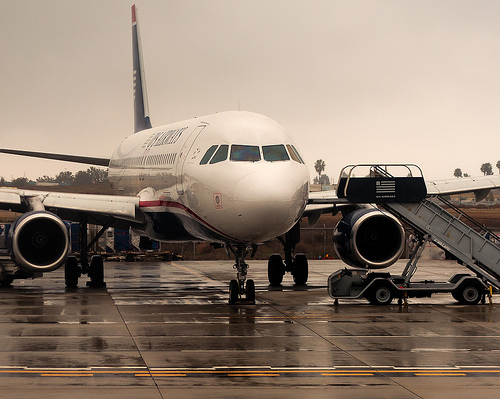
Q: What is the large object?
A: Plane.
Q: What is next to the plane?
A: Steps.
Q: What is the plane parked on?
A: Tarmac.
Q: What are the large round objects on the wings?
A: Engines.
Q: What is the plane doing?
A: Parked.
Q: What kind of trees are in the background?
A: Palm.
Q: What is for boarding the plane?
A: The stairs.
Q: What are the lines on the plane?
A: Yellow and white.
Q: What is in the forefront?
A: The airplane.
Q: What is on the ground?
A: The airplane.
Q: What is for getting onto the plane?
A: The stairway.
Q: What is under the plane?
A: Wet ground.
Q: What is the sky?
A: Grey white.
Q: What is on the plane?
A: Landing wheels.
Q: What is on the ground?
A: Yellow and white lines.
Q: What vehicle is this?
A: Plane.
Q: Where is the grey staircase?
A: Right of plane.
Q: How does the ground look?
A: Wet.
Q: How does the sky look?
A: Cloudy.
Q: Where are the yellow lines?
A: On the ground.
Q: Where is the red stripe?
A: On the plane.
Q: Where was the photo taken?
A: Airport.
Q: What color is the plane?
A: White.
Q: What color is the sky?
A: Gray.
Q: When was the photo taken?
A: Daytime.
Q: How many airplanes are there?
A: One.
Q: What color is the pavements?
A: Dark Gray.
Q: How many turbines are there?
A: Two.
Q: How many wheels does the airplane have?
A: Six.